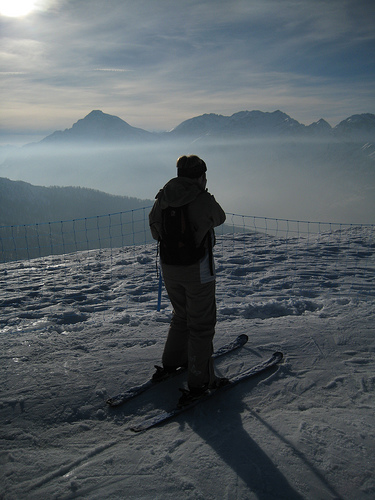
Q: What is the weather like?
A: It is cloudy.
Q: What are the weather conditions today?
A: It is cloudy.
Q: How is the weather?
A: It is cloudy.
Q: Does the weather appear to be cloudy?
A: Yes, it is cloudy.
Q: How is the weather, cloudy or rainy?
A: It is cloudy.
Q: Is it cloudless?
A: No, it is cloudy.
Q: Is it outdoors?
A: Yes, it is outdoors.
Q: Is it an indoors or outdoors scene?
A: It is outdoors.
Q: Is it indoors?
A: No, it is outdoors.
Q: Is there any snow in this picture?
A: Yes, there is snow.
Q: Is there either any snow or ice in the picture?
A: Yes, there is snow.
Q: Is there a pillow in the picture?
A: No, there are no pillows.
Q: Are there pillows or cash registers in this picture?
A: No, there are no pillows or cash registers.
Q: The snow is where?
A: The snow is on the hill.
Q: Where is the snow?
A: The snow is on the hill.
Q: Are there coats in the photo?
A: Yes, there is a coat.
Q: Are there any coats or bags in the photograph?
A: Yes, there is a coat.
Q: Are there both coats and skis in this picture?
A: Yes, there are both a coat and skis.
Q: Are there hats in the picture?
A: Yes, there is a hat.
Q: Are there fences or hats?
A: Yes, there is a hat.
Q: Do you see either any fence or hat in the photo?
A: Yes, there is a hat.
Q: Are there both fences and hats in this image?
A: Yes, there are both a hat and a fence.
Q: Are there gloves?
A: No, there are no gloves.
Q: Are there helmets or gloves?
A: No, there are no gloves or helmets.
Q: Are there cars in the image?
A: No, there are no cars.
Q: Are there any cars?
A: No, there are no cars.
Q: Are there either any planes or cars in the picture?
A: No, there are no cars or planes.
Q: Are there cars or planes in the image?
A: No, there are no cars or planes.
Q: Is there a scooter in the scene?
A: No, there are no scooters.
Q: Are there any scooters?
A: No, there are no scooters.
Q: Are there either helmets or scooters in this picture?
A: No, there are no scooters or helmets.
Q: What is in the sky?
A: The sun is in the sky.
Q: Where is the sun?
A: The sun is in the sky.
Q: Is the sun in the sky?
A: Yes, the sun is in the sky.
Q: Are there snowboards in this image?
A: No, there are no snowboards.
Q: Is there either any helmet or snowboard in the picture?
A: No, there are no snowboards or helmets.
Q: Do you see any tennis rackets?
A: No, there are no tennis rackets.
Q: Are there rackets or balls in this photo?
A: No, there are no rackets or balls.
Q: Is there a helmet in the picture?
A: No, there are no helmets.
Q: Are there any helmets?
A: No, there are no helmets.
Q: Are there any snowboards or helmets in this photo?
A: No, there are no helmets or snowboards.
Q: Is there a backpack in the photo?
A: Yes, there is a backpack.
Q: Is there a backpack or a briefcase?
A: Yes, there is a backpack.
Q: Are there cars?
A: No, there are no cars.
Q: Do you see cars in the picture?
A: No, there are no cars.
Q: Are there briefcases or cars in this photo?
A: No, there are no cars or briefcases.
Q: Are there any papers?
A: No, there are no papers.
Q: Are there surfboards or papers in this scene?
A: No, there are no papers or surfboards.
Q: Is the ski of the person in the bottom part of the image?
A: Yes, the ski is in the bottom of the image.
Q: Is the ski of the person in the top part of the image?
A: No, the ski is in the bottom of the image.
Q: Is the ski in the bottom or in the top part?
A: The ski is in the bottom of the image.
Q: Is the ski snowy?
A: Yes, the ski is snowy.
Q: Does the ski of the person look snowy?
A: Yes, the ski is snowy.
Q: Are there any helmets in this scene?
A: No, there are no helmets.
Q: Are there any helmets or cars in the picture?
A: No, there are no helmets or cars.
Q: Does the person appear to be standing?
A: Yes, the person is standing.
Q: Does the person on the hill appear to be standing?
A: Yes, the person is standing.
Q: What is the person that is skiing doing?
A: The person is standing.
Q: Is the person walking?
A: No, the person is standing.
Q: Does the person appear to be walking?
A: No, the person is standing.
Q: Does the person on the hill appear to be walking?
A: No, the person is standing.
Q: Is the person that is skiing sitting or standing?
A: The person is standing.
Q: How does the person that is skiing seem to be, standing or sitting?
A: The person is standing.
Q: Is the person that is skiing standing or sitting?
A: The person is standing.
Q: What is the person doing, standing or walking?
A: The person is standing.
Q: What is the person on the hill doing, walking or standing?
A: The person is standing.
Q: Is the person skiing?
A: Yes, the person is skiing.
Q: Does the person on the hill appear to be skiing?
A: Yes, the person is skiing.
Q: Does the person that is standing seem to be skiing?
A: Yes, the person is skiing.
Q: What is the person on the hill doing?
A: The person is skiing.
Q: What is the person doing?
A: The person is skiing.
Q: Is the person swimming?
A: No, the person is skiing.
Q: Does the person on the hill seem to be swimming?
A: No, the person is skiing.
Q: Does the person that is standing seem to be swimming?
A: No, the person is skiing.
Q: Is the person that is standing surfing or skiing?
A: The person is skiing.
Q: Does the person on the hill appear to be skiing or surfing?
A: The person is skiing.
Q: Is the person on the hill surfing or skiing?
A: The person is skiing.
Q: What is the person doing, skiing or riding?
A: The person is skiing.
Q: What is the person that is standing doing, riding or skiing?
A: The person is skiing.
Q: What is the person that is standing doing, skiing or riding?
A: The person is skiing.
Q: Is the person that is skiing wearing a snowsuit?
A: Yes, the person is wearing a snowsuit.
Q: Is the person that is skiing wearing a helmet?
A: No, the person is wearing a snowsuit.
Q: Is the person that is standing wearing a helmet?
A: No, the person is wearing a snowsuit.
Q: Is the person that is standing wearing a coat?
A: Yes, the person is wearing a coat.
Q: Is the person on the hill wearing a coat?
A: Yes, the person is wearing a coat.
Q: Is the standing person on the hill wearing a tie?
A: No, the person is wearing a coat.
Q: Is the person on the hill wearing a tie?
A: No, the person is wearing a coat.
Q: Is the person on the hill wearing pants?
A: Yes, the person is wearing pants.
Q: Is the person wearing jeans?
A: No, the person is wearing pants.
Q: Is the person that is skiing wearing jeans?
A: No, the person is wearing pants.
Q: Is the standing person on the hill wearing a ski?
A: Yes, the person is wearing a ski.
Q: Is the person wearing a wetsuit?
A: No, the person is wearing a ski.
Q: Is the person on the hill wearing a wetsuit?
A: No, the person is wearing a ski.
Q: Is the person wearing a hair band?
A: Yes, the person is wearing a hair band.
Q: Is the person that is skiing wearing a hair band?
A: Yes, the person is wearing a hair band.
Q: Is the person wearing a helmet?
A: No, the person is wearing a hair band.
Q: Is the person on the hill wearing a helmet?
A: No, the person is wearing a hair band.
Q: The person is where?
A: The person is on the hill.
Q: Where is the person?
A: The person is on the hill.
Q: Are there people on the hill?
A: Yes, there is a person on the hill.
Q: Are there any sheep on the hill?
A: No, there is a person on the hill.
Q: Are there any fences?
A: Yes, there is a fence.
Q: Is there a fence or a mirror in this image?
A: Yes, there is a fence.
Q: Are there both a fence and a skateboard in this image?
A: No, there is a fence but no skateboards.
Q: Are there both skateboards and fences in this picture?
A: No, there is a fence but no skateboards.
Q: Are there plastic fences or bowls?
A: Yes, there is a plastic fence.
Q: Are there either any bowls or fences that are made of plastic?
A: Yes, the fence is made of plastic.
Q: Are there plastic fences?
A: Yes, there is a fence that is made of plastic.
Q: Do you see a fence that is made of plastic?
A: Yes, there is a fence that is made of plastic.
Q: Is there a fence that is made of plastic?
A: Yes, there is a fence that is made of plastic.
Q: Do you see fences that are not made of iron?
A: Yes, there is a fence that is made of plastic.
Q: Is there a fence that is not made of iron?
A: Yes, there is a fence that is made of plastic.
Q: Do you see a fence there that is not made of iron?
A: Yes, there is a fence that is made of plastic.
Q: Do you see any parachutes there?
A: No, there are no parachutes.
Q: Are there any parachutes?
A: No, there are no parachutes.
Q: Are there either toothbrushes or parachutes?
A: No, there are no parachutes or toothbrushes.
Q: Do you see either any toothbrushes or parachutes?
A: No, there are no parachutes or toothbrushes.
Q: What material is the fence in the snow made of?
A: The fence is made of plastic.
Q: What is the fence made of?
A: The fence is made of plastic.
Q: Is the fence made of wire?
A: No, the fence is made of plastic.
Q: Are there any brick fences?
A: No, there is a fence but it is made of plastic.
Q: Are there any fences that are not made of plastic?
A: No, there is a fence but it is made of plastic.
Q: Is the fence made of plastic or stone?
A: The fence is made of plastic.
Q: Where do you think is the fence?
A: The fence is in the snow.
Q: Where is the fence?
A: The fence is in the snow.